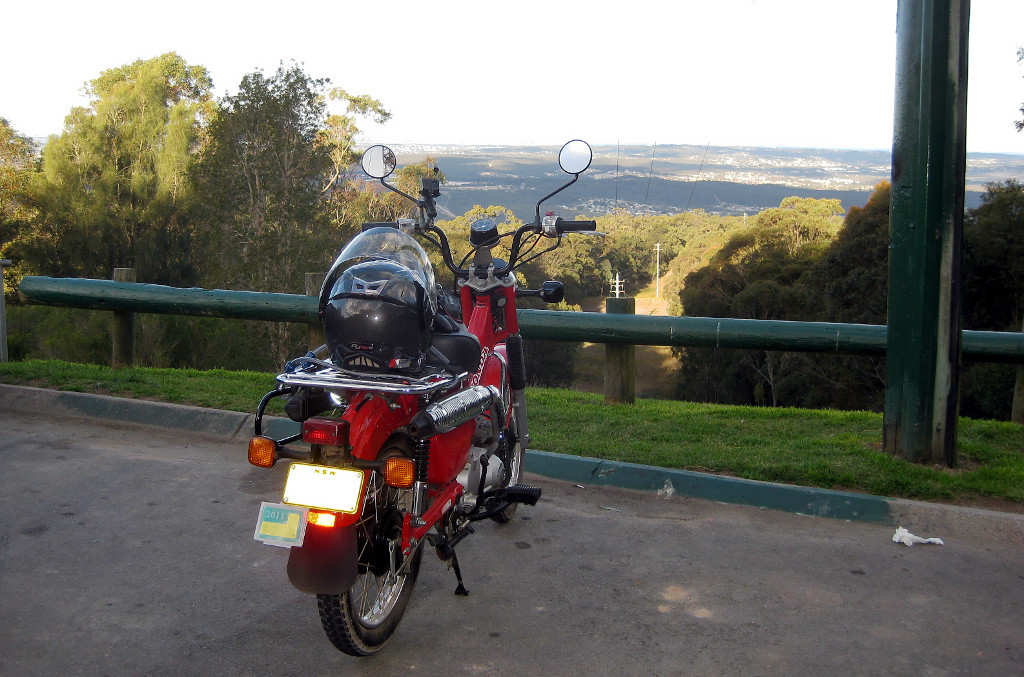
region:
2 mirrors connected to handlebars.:
[344, 138, 623, 236]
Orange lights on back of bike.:
[227, 430, 433, 489]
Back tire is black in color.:
[306, 430, 427, 653]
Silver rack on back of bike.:
[296, 361, 440, 415]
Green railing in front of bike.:
[22, 247, 997, 372]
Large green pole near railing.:
[872, 23, 965, 441]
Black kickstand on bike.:
[438, 538, 476, 618]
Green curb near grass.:
[108, 380, 897, 539]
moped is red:
[239, 184, 600, 671]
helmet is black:
[298, 226, 460, 376]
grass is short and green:
[694, 400, 806, 490]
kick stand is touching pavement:
[438, 536, 470, 595]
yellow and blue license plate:
[245, 494, 309, 549]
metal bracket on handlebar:
[523, 194, 566, 243]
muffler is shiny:
[397, 374, 511, 445]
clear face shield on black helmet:
[324, 223, 438, 275]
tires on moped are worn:
[316, 594, 373, 668]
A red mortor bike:
[236, 140, 604, 654]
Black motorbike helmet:
[294, 212, 454, 390]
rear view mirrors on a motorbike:
[312, 129, 622, 202]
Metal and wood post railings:
[540, 282, 980, 438]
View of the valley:
[335, 111, 1016, 257]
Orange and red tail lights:
[237, 410, 434, 494]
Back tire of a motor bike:
[313, 511, 431, 663]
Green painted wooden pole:
[865, 3, 1002, 493]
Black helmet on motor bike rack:
[240, 222, 503, 451]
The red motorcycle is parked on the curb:
[57, 42, 785, 650]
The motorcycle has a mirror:
[443, 78, 687, 638]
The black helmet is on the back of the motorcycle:
[143, 127, 676, 615]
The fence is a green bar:
[35, 253, 911, 469]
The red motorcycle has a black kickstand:
[187, 38, 706, 634]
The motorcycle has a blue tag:
[175, 300, 471, 652]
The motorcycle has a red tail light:
[178, 69, 698, 674]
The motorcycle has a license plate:
[207, 281, 607, 665]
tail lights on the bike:
[222, 426, 437, 504]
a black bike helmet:
[304, 211, 495, 379]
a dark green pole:
[873, 10, 992, 492]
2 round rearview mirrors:
[324, 124, 647, 214]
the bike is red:
[204, 98, 775, 674]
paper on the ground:
[874, 500, 947, 570]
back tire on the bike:
[258, 426, 455, 655]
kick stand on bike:
[416, 487, 503, 631]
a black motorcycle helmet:
[311, 262, 439, 379]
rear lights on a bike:
[242, 428, 420, 489]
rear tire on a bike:
[312, 507, 420, 644]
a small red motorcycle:
[238, 112, 621, 672]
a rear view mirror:
[557, 139, 596, 179]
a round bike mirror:
[359, 140, 397, 185]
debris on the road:
[889, 519, 951, 551]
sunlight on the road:
[640, 563, 732, 627]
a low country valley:
[396, 140, 967, 235]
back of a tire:
[155, 514, 522, 673]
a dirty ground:
[561, 588, 953, 662]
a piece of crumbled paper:
[828, 469, 964, 594]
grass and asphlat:
[73, 355, 225, 606]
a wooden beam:
[783, 416, 927, 534]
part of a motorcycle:
[240, 486, 317, 557]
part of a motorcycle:
[275, 451, 381, 518]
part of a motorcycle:
[297, 505, 367, 540]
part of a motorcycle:
[429, 537, 480, 601]